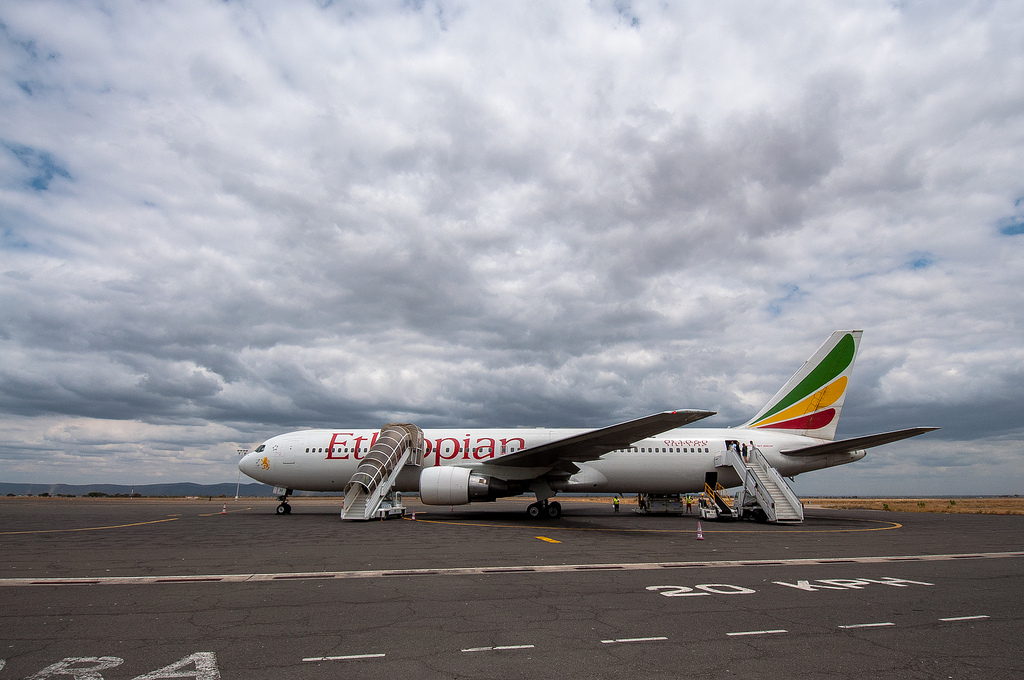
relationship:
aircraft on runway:
[238, 327, 944, 524] [242, 511, 772, 651]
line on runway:
[576, 620, 702, 674] [242, 511, 772, 651]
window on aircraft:
[653, 435, 673, 466] [238, 327, 944, 524]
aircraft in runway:
[238, 327, 944, 524] [242, 511, 772, 651]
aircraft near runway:
[238, 327, 944, 524] [242, 511, 772, 651]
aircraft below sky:
[238, 327, 944, 524] [191, 101, 850, 299]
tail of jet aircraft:
[741, 308, 940, 483] [214, 333, 951, 582]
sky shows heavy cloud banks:
[91, 256, 967, 391] [97, 206, 983, 343]